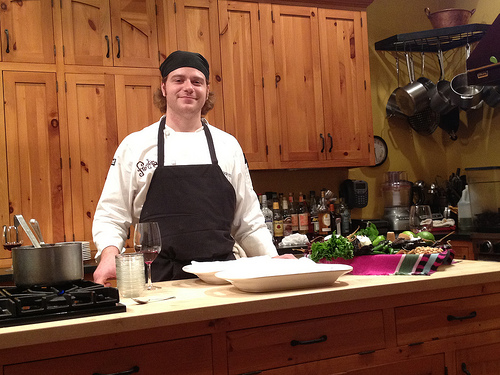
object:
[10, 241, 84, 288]
pot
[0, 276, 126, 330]
stove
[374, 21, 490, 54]
rack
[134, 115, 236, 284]
apron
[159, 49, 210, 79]
bandana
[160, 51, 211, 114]
man's head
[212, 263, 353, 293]
tray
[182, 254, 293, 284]
tray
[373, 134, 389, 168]
clock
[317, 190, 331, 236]
bottle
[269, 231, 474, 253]
counter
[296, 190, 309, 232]
bottle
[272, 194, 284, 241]
bottle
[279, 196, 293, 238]
bottle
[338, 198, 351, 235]
bottle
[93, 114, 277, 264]
shirt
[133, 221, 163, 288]
glass of wine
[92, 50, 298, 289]
man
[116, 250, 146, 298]
can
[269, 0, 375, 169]
cabinet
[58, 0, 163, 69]
cabinet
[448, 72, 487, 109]
pot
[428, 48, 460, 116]
pot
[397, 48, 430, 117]
pot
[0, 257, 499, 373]
table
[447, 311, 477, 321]
handle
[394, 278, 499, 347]
drawer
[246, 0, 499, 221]
wall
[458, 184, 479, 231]
gallon jug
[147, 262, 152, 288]
stem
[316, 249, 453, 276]
tray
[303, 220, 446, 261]
fresh vegetables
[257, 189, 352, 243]
group of bottles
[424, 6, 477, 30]
cooking ware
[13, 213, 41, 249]
spoon